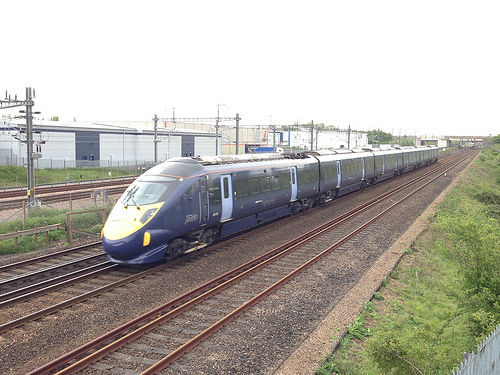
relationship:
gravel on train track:
[1, 129, 481, 372] [31, 153, 477, 373]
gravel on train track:
[1, 129, 481, 372] [9, 226, 194, 373]